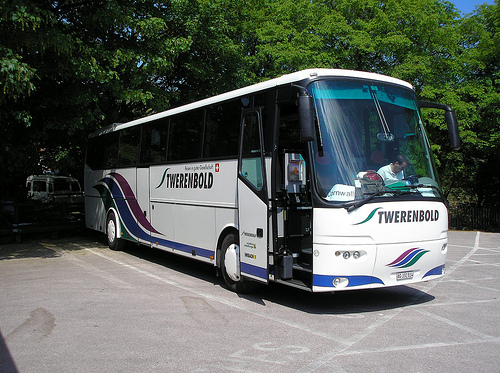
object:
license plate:
[389, 269, 424, 289]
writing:
[164, 170, 216, 191]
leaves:
[9, 6, 56, 101]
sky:
[447, 0, 483, 15]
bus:
[82, 67, 464, 295]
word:
[375, 208, 442, 224]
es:
[227, 335, 310, 366]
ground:
[1, 297, 86, 370]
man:
[377, 153, 411, 186]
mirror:
[416, 97, 465, 155]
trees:
[3, 2, 84, 168]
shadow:
[137, 247, 437, 317]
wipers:
[367, 86, 394, 137]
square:
[212, 160, 222, 172]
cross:
[214, 163, 219, 169]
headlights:
[331, 240, 369, 257]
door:
[233, 101, 275, 291]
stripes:
[118, 169, 161, 245]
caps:
[214, 225, 248, 292]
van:
[20, 173, 84, 205]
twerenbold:
[163, 170, 216, 189]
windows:
[84, 87, 283, 163]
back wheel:
[101, 207, 124, 249]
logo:
[350, 205, 440, 225]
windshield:
[306, 77, 447, 204]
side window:
[95, 129, 120, 169]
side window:
[141, 116, 169, 166]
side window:
[166, 106, 206, 162]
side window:
[200, 94, 244, 158]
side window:
[251, 90, 275, 153]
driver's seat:
[362, 150, 388, 172]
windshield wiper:
[344, 189, 420, 212]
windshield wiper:
[390, 183, 445, 195]